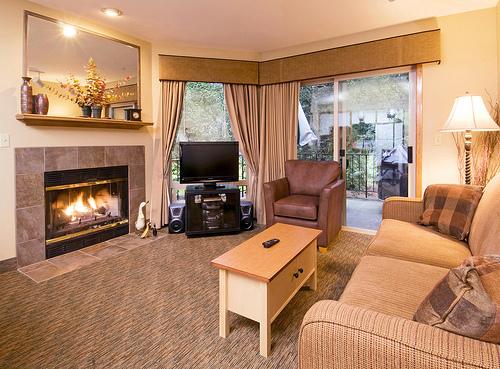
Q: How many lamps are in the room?
A: 1.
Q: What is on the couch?
A: Pillows.